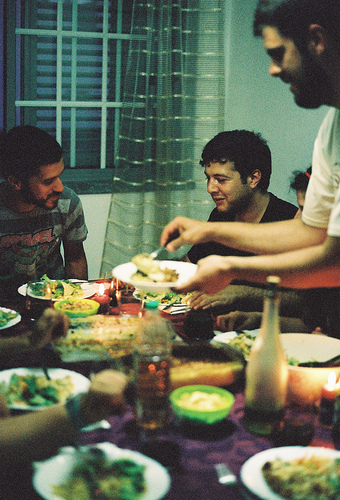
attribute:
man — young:
[177, 127, 303, 272]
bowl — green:
[169, 383, 235, 432]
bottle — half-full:
[245, 276, 289, 435]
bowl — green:
[170, 378, 235, 428]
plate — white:
[239, 443, 339, 498]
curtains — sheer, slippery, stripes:
[102, 6, 234, 289]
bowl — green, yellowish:
[170, 383, 234, 423]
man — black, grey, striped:
[9, 123, 94, 266]